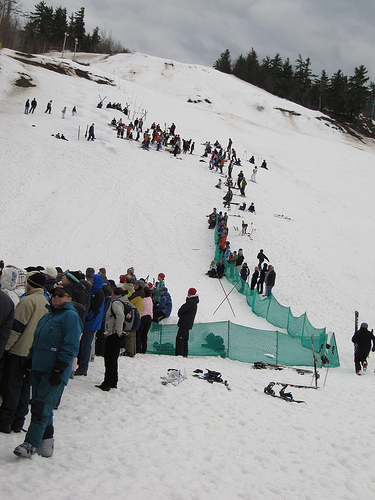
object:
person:
[99, 267, 109, 283]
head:
[98, 268, 106, 280]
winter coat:
[202, 150, 225, 170]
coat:
[157, 292, 172, 317]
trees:
[2, 1, 119, 54]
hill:
[102, 55, 232, 107]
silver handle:
[174, 326, 190, 359]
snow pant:
[23, 367, 65, 448]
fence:
[150, 322, 174, 355]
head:
[157, 272, 165, 282]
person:
[152, 272, 166, 305]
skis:
[263, 381, 317, 405]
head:
[359, 322, 368, 330]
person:
[350, 322, 375, 377]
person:
[175, 287, 200, 358]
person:
[263, 264, 277, 297]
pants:
[352, 349, 369, 374]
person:
[44, 98, 53, 114]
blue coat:
[26, 299, 84, 387]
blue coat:
[83, 273, 106, 331]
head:
[49, 279, 74, 308]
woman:
[98, 283, 128, 398]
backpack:
[109, 296, 135, 336]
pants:
[100, 333, 121, 389]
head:
[186, 287, 196, 295]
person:
[0, 271, 51, 435]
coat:
[4, 287, 51, 358]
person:
[12, 282, 83, 460]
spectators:
[0, 184, 374, 463]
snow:
[177, 395, 252, 446]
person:
[94, 283, 142, 392]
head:
[111, 286, 124, 300]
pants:
[0, 353, 34, 426]